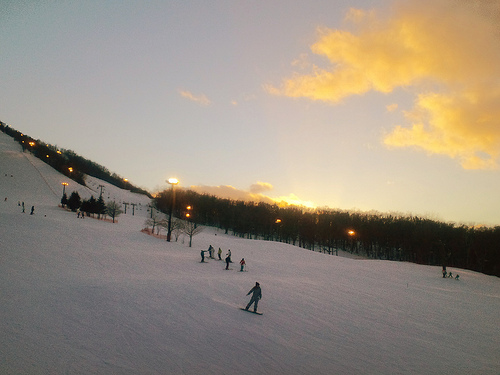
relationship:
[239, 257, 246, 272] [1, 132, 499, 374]
skier on slope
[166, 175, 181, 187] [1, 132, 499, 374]
light on slope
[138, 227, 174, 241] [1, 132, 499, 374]
fence on slope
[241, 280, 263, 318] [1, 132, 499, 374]
boarder on slope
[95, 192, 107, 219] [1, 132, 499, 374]
tree on slope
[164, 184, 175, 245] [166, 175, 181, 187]
pole with light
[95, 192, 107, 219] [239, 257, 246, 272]
tree behind skier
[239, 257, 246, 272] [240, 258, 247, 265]
skier has a jacket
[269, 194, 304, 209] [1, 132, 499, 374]
sun behind slope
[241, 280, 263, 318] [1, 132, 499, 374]
boarder down slope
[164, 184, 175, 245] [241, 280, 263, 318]
pole by boarder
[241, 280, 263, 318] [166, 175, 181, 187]
boarder by light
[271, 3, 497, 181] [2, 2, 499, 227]
cloud in sky